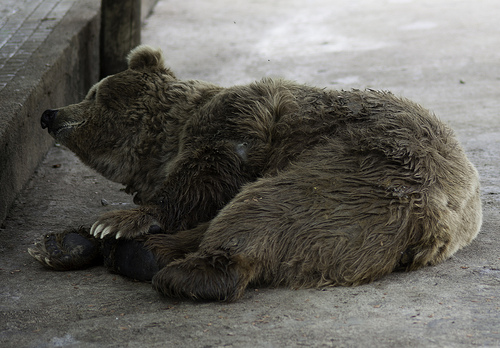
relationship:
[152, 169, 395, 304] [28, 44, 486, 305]
leg of bear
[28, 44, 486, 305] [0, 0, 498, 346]
bear laying on ground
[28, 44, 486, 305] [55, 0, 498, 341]
bear laying on ground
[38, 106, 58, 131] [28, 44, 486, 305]
nose of bear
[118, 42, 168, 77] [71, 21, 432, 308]
ear of bear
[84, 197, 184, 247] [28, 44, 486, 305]
paw of bear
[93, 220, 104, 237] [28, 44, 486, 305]
claw of bear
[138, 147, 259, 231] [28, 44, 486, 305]
legs of bear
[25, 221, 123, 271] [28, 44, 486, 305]
legs of bear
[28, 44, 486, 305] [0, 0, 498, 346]
bear on ground